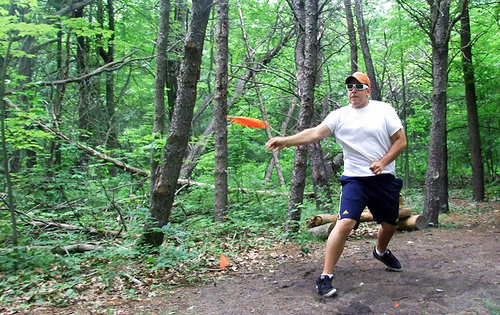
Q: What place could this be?
A: It is a forest.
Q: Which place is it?
A: It is a forest.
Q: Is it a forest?
A: Yes, it is a forest.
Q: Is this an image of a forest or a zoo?
A: It is showing a forest.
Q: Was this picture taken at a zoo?
A: No, the picture was taken in a forest.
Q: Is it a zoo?
A: No, it is a forest.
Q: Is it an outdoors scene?
A: Yes, it is outdoors.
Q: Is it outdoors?
A: Yes, it is outdoors.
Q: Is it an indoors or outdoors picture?
A: It is outdoors.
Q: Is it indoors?
A: No, it is outdoors.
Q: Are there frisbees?
A: Yes, there is a frisbee.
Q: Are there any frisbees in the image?
A: Yes, there is a frisbee.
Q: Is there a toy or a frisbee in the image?
A: Yes, there is a frisbee.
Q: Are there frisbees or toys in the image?
A: Yes, there is a frisbee.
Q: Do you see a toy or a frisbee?
A: Yes, there is a frisbee.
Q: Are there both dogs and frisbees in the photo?
A: No, there is a frisbee but no dogs.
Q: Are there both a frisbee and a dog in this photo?
A: No, there is a frisbee but no dogs.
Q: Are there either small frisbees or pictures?
A: Yes, there is a small frisbee.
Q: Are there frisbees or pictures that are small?
A: Yes, the frisbee is small.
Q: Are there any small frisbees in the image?
A: Yes, there is a small frisbee.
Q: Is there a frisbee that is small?
A: Yes, there is a frisbee that is small.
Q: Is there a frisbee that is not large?
A: Yes, there is a small frisbee.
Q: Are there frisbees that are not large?
A: Yes, there is a small frisbee.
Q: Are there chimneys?
A: No, there are no chimneys.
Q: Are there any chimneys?
A: No, there are no chimneys.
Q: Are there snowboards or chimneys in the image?
A: No, there are no chimneys or snowboards.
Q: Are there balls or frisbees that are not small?
A: No, there is a frisbee but it is small.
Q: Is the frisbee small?
A: Yes, the frisbee is small.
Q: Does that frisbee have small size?
A: Yes, the frisbee is small.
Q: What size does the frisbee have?
A: The frisbee has small size.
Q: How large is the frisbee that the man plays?
A: The frisbee is small.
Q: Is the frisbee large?
A: No, the frisbee is small.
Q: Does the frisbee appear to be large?
A: No, the frisbee is small.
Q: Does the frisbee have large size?
A: No, the frisbee is small.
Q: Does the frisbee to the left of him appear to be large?
A: No, the frisbee is small.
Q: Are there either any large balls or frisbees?
A: No, there is a frisbee but it is small.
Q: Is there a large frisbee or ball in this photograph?
A: No, there is a frisbee but it is small.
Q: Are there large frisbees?
A: No, there is a frisbee but it is small.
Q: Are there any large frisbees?
A: No, there is a frisbee but it is small.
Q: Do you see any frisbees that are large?
A: No, there is a frisbee but it is small.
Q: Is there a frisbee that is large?
A: No, there is a frisbee but it is small.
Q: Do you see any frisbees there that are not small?
A: No, there is a frisbee but it is small.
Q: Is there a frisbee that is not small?
A: No, there is a frisbee but it is small.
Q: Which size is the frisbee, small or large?
A: The frisbee is small.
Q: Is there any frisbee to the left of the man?
A: Yes, there is a frisbee to the left of the man.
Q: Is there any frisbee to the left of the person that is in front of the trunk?
A: Yes, there is a frisbee to the left of the man.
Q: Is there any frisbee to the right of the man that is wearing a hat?
A: No, the frisbee is to the left of the man.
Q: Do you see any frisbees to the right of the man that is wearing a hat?
A: No, the frisbee is to the left of the man.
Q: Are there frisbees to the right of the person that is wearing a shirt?
A: No, the frisbee is to the left of the man.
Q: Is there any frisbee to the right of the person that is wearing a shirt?
A: No, the frisbee is to the left of the man.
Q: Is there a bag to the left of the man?
A: No, there is a frisbee to the left of the man.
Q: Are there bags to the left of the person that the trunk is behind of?
A: No, there is a frisbee to the left of the man.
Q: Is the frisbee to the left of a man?
A: Yes, the frisbee is to the left of a man.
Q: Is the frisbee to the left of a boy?
A: No, the frisbee is to the left of a man.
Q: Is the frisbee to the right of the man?
A: No, the frisbee is to the left of the man.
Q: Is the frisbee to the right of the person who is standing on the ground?
A: No, the frisbee is to the left of the man.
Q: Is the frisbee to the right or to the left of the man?
A: The frisbee is to the left of the man.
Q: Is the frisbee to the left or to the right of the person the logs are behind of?
A: The frisbee is to the left of the man.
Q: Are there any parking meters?
A: No, there are no parking meters.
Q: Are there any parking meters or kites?
A: No, there are no parking meters or kites.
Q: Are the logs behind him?
A: Yes, the logs are behind a man.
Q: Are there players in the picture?
A: No, there are no players.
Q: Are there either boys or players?
A: No, there are no players or boys.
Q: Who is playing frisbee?
A: The man is playing frisbee.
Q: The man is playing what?
A: The man is playing frisbee.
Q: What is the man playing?
A: The man is playing frisbee.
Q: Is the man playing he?
A: Yes, the man is playing frisbee.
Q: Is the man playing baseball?
A: No, the man is playing frisbee.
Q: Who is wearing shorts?
A: The man is wearing shorts.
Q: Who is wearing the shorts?
A: The man is wearing shorts.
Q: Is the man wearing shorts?
A: Yes, the man is wearing shorts.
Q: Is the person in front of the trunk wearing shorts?
A: Yes, the man is wearing shorts.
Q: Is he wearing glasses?
A: No, the man is wearing shorts.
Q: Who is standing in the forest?
A: The man is standing in the forest.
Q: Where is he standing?
A: The man is standing in the forest.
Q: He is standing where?
A: The man is standing in the forest.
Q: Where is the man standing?
A: The man is standing in the forest.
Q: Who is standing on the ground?
A: The man is standing on the ground.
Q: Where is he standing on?
A: The man is standing on the ground.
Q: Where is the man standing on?
A: The man is standing on the ground.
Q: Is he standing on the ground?
A: Yes, the man is standing on the ground.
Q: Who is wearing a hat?
A: The man is wearing a hat.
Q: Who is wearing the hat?
A: The man is wearing a hat.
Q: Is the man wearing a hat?
A: Yes, the man is wearing a hat.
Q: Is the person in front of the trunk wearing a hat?
A: Yes, the man is wearing a hat.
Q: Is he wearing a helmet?
A: No, the man is wearing a hat.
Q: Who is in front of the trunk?
A: The man is in front of the trunk.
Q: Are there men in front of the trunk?
A: Yes, there is a man in front of the trunk.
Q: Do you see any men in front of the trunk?
A: Yes, there is a man in front of the trunk.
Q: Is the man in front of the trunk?
A: Yes, the man is in front of the trunk.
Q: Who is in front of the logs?
A: The man is in front of the logs.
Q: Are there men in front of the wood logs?
A: Yes, there is a man in front of the logs.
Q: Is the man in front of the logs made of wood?
A: Yes, the man is in front of the logs.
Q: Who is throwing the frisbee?
A: The man is throwing the frisbee.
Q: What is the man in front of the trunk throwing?
A: The man is throwing the frisbee.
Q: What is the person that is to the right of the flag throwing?
A: The man is throwing the frisbee.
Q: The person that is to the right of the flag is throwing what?
A: The man is throwing the frisbee.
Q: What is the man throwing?
A: The man is throwing the frisbee.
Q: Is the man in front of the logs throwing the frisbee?
A: Yes, the man is throwing the frisbee.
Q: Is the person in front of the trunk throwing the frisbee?
A: Yes, the man is throwing the frisbee.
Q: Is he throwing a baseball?
A: No, the man is throwing the frisbee.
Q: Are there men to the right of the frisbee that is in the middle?
A: Yes, there is a man to the right of the frisbee.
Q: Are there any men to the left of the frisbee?
A: No, the man is to the right of the frisbee.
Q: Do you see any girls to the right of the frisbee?
A: No, there is a man to the right of the frisbee.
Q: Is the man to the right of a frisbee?
A: Yes, the man is to the right of a frisbee.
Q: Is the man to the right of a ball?
A: No, the man is to the right of a frisbee.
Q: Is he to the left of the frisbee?
A: No, the man is to the right of the frisbee.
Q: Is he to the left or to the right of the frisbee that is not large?
A: The man is to the right of the frisbee.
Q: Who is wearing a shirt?
A: The man is wearing a shirt.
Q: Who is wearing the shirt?
A: The man is wearing a shirt.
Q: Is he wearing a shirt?
A: Yes, the man is wearing a shirt.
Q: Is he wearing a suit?
A: No, the man is wearing a shirt.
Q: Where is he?
A: The man is in the forest.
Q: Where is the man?
A: The man is in the forest.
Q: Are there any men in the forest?
A: Yes, there is a man in the forest.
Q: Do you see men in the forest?
A: Yes, there is a man in the forest.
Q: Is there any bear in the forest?
A: No, there is a man in the forest.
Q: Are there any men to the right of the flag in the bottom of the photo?
A: Yes, there is a man to the right of the flag.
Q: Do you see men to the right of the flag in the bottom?
A: Yes, there is a man to the right of the flag.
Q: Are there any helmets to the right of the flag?
A: No, there is a man to the right of the flag.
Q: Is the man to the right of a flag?
A: Yes, the man is to the right of a flag.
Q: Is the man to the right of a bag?
A: No, the man is to the right of a flag.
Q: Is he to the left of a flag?
A: No, the man is to the right of a flag.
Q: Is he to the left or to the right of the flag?
A: The man is to the right of the flag.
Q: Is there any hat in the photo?
A: Yes, there is a hat.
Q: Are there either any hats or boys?
A: Yes, there is a hat.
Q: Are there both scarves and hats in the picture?
A: No, there is a hat but no scarves.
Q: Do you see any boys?
A: No, there are no boys.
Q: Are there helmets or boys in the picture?
A: No, there are no boys or helmets.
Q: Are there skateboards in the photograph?
A: No, there are no skateboards.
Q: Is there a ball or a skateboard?
A: No, there are no skateboards or balls.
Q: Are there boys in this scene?
A: No, there are no boys.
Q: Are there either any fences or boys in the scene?
A: No, there are no boys or fences.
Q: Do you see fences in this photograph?
A: No, there are no fences.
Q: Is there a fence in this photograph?
A: No, there are no fences.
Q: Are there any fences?
A: No, there are no fences.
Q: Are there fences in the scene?
A: No, there are no fences.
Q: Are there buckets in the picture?
A: No, there are no buckets.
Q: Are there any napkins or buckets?
A: No, there are no buckets or napkins.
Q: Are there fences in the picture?
A: No, there are no fences.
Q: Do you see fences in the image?
A: No, there are no fences.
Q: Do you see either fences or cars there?
A: No, there are no fences or cars.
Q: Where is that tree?
A: The tree is in the forest.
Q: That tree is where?
A: The tree is in the forest.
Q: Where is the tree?
A: The tree is in the forest.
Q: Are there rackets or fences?
A: No, there are no fences or rackets.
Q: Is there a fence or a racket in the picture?
A: No, there are no fences or rackets.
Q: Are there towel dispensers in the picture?
A: No, there are no towel dispensers.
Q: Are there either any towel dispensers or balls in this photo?
A: No, there are no towel dispensers or balls.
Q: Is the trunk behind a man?
A: Yes, the trunk is behind a man.